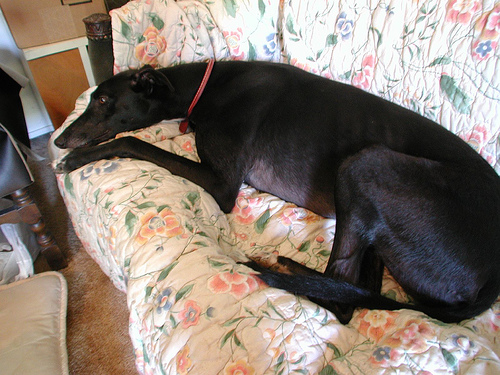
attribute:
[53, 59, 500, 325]
dog — black, laying, shiny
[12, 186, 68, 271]
leg — brown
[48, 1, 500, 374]
couch — pink, green, here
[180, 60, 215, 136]
collar — red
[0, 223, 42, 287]
bag — white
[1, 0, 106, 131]
wall — tan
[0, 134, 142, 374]
carpet — tan, brown, beige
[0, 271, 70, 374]
pillow — here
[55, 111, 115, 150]
snout — black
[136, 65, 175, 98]
ear — floppy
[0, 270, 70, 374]
cushion — tan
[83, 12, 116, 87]
canister — brown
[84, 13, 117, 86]
post — wooden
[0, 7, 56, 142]
door — light